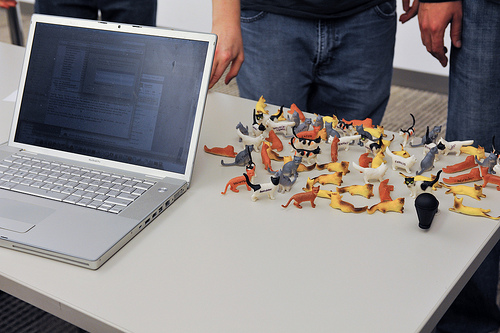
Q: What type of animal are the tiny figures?
A: Cats.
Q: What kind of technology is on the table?
A: A laptop.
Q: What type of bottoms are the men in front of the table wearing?
A: Jeans.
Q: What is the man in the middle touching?
A: The table.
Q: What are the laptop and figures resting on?
A: The table.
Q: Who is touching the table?
A: The man in the middle.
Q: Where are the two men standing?
A: In front of the table.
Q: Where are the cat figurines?
A: On the table.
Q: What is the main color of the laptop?
A: Silver.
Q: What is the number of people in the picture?
A: 2.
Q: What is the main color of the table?
A: White.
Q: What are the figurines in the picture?
A: Cats.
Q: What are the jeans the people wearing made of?
A: Denim.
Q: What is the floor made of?
A: Carpet.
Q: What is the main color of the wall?
A: White.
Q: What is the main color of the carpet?
A: Brown.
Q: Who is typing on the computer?
A: Nobody.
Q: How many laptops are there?
A: 1.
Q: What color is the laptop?
A: Silver.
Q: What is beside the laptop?
A: Figurines.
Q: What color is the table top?
A: White.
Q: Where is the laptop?
A: On the table.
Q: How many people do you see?
A: 3.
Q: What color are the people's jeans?
A: Blue.